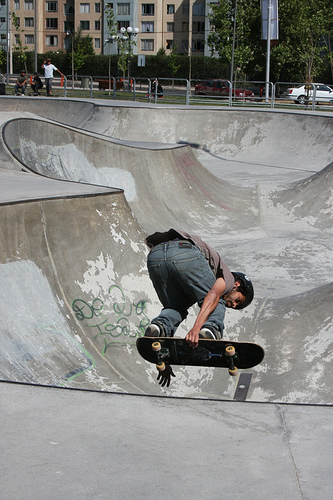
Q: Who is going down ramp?
A: Skateboarder.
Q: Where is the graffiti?
A: On ramp.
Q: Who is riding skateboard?
A: A boy.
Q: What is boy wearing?
A: Jeans.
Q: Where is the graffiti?
A: On wall.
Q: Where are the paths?
A: The skatepark.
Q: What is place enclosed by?
A: Fence.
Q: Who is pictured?
A: A man.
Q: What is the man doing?
A: Skateboarding.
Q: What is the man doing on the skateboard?
A: A trick.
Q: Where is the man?
A: Skate park.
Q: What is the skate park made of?
A: Concrete.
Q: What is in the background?
A: A metal fence.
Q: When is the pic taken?
A: Daytime.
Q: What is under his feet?
A: A skateboard.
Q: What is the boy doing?
A: Skateboarding.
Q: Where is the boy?
A: A skatepark.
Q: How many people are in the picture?
A: 1.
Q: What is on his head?
A: A helmet.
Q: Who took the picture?
A: The photographer.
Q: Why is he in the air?
A: He ramped.